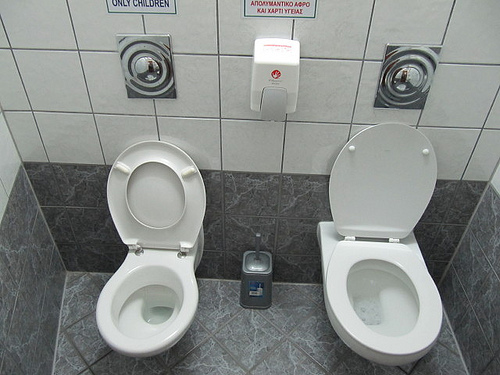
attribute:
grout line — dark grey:
[11, 43, 79, 53]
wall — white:
[6, 22, 128, 162]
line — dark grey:
[96, 108, 155, 123]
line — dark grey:
[0, 97, 497, 162]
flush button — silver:
[362, 30, 447, 121]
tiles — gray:
[29, 24, 92, 147]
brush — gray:
[254, 234, 261, 261]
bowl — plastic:
[240, 230, 274, 307]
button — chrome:
[388, 66, 422, 95]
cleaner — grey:
[230, 220, 281, 317]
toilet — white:
[292, 117, 469, 361]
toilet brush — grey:
[242, 232, 277, 312]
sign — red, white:
[243, 0, 316, 17]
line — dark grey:
[284, 117, 349, 126]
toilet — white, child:
[93, 139, 208, 358]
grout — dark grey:
[217, 124, 240, 169]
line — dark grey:
[226, 108, 263, 128]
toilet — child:
[69, 135, 223, 368]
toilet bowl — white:
[94, 250, 200, 357]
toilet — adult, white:
[318, 120, 446, 369]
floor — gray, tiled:
[50, 270, 465, 374]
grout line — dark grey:
[82, 90, 106, 155]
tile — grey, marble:
[223, 170, 282, 218]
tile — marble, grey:
[209, 310, 289, 372]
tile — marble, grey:
[55, 327, 90, 373]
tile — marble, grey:
[442, 181, 488, 228]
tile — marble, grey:
[66, 208, 121, 249]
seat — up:
[95, 149, 236, 247]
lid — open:
[327, 122, 443, 237]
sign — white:
[240, 2, 322, 20]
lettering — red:
[248, 2, 308, 14]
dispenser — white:
[248, 37, 304, 120]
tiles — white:
[223, 310, 315, 361]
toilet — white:
[323, 135, 445, 350]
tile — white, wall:
[151, 50, 222, 121]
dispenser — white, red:
[245, 33, 301, 121]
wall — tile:
[2, 1, 484, 301]